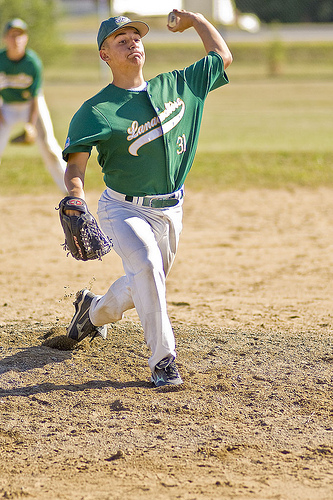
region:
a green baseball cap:
[95, 15, 149, 46]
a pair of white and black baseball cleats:
[67, 290, 180, 386]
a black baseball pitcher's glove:
[57, 197, 111, 260]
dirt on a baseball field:
[184, 313, 290, 441]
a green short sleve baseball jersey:
[63, 51, 228, 197]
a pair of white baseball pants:
[88, 190, 183, 370]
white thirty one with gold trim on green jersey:
[172, 133, 189, 154]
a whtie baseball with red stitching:
[166, 11, 181, 27]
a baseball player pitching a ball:
[55, 7, 233, 387]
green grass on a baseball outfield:
[57, 85, 302, 172]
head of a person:
[91, 4, 150, 82]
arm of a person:
[177, 13, 237, 61]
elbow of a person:
[56, 167, 105, 189]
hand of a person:
[48, 207, 106, 233]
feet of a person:
[58, 269, 102, 347]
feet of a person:
[144, 357, 198, 410]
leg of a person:
[87, 214, 190, 358]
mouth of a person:
[112, 52, 147, 70]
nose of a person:
[126, 34, 140, 51]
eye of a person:
[112, 34, 131, 51]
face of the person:
[95, 17, 167, 77]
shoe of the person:
[140, 356, 205, 404]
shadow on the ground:
[34, 373, 111, 406]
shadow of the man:
[33, 372, 147, 399]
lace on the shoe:
[160, 358, 179, 370]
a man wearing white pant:
[95, 212, 238, 333]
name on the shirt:
[112, 93, 211, 168]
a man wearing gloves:
[56, 189, 120, 275]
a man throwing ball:
[158, 0, 201, 30]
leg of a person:
[118, 237, 173, 353]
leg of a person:
[104, 261, 150, 316]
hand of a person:
[167, 13, 199, 36]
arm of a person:
[195, 1, 248, 71]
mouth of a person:
[119, 45, 151, 67]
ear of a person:
[96, 46, 112, 68]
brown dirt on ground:
[28, 436, 40, 445]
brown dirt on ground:
[85, 429, 108, 442]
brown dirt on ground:
[110, 424, 125, 439]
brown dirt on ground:
[197, 422, 225, 458]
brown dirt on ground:
[232, 402, 260, 426]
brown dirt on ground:
[254, 372, 276, 392]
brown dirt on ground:
[213, 362, 234, 381]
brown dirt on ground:
[271, 357, 287, 384]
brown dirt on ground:
[215, 357, 233, 368]